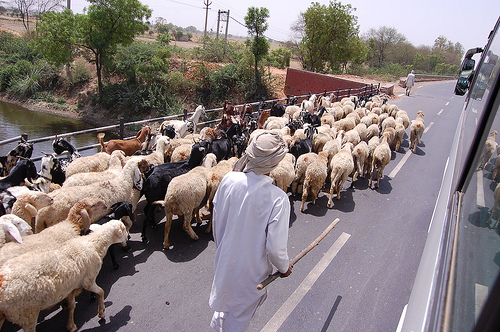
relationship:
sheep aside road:
[42, 82, 393, 278] [414, 75, 473, 130]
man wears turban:
[215, 150, 291, 329] [233, 137, 281, 185]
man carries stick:
[215, 150, 291, 329] [270, 207, 337, 288]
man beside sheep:
[215, 150, 291, 329] [42, 82, 393, 278]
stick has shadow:
[270, 207, 337, 288] [311, 285, 343, 331]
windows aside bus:
[428, 127, 497, 330] [448, 61, 496, 331]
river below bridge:
[3, 112, 95, 168] [16, 49, 494, 314]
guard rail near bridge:
[2, 85, 358, 149] [16, 49, 494, 314]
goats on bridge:
[8, 84, 388, 294] [16, 49, 494, 314]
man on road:
[406, 65, 428, 90] [414, 75, 473, 130]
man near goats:
[215, 150, 291, 329] [8, 84, 388, 294]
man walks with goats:
[215, 150, 291, 329] [8, 84, 388, 294]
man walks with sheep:
[215, 150, 291, 329] [42, 82, 393, 278]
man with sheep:
[215, 150, 291, 329] [42, 82, 393, 278]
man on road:
[215, 150, 291, 329] [414, 75, 473, 130]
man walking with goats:
[215, 150, 291, 329] [8, 84, 388, 294]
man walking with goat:
[215, 150, 291, 329] [128, 144, 218, 226]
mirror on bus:
[450, 117, 498, 292] [448, 61, 496, 331]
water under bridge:
[3, 112, 95, 168] [16, 49, 494, 314]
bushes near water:
[22, 25, 293, 114] [3, 112, 95, 168]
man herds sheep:
[215, 150, 291, 329] [42, 82, 393, 278]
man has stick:
[215, 150, 291, 329] [270, 207, 337, 288]